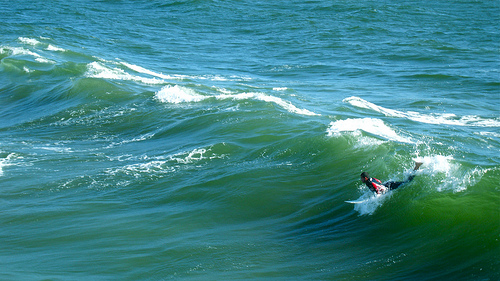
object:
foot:
[414, 161, 423, 170]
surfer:
[359, 162, 423, 194]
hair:
[360, 171, 370, 179]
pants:
[384, 172, 417, 192]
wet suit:
[364, 174, 415, 195]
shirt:
[366, 177, 389, 193]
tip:
[343, 200, 356, 204]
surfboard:
[342, 191, 382, 204]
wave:
[0, 35, 499, 239]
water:
[2, 1, 498, 281]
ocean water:
[1, 1, 342, 281]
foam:
[152, 84, 208, 103]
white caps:
[0, 34, 204, 109]